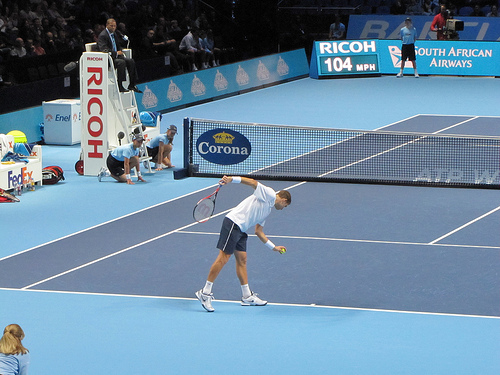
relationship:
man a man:
[180, 168, 303, 314] [195, 174, 292, 311]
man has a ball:
[180, 168, 303, 314] [266, 234, 298, 255]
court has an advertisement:
[0, 74, 498, 374] [195, 127, 252, 165]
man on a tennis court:
[195, 174, 292, 311] [39, 76, 482, 317]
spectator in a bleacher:
[183, 27, 199, 53] [21, 68, 66, 89]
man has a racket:
[195, 174, 292, 311] [191, 167, 229, 229]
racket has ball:
[191, 167, 229, 229] [280, 248, 286, 254]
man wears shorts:
[195, 174, 292, 311] [215, 217, 249, 255]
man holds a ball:
[195, 174, 292, 311] [275, 239, 298, 261]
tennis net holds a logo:
[178, 111, 499, 192] [191, 123, 256, 168]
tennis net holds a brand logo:
[178, 111, 499, 192] [195, 120, 264, 170]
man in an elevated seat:
[94, 12, 156, 104] [71, 68, 167, 160]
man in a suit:
[94, 12, 156, 104] [88, 33, 129, 56]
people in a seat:
[93, 120, 180, 185] [92, 114, 186, 182]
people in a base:
[93, 120, 180, 185] [67, 48, 156, 188]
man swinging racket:
[195, 174, 292, 311] [193, 174, 229, 223]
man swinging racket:
[195, 174, 292, 311] [192, 181, 221, 226]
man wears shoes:
[195, 174, 292, 311] [194, 280, 265, 313]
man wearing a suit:
[96, 18, 142, 94] [89, 18, 146, 97]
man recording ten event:
[428, 3, 455, 41] [79, 94, 484, 319]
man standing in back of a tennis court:
[431, 5, 460, 41] [133, 98, 454, 337]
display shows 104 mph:
[317, 51, 381, 76] [323, 54, 377, 74]